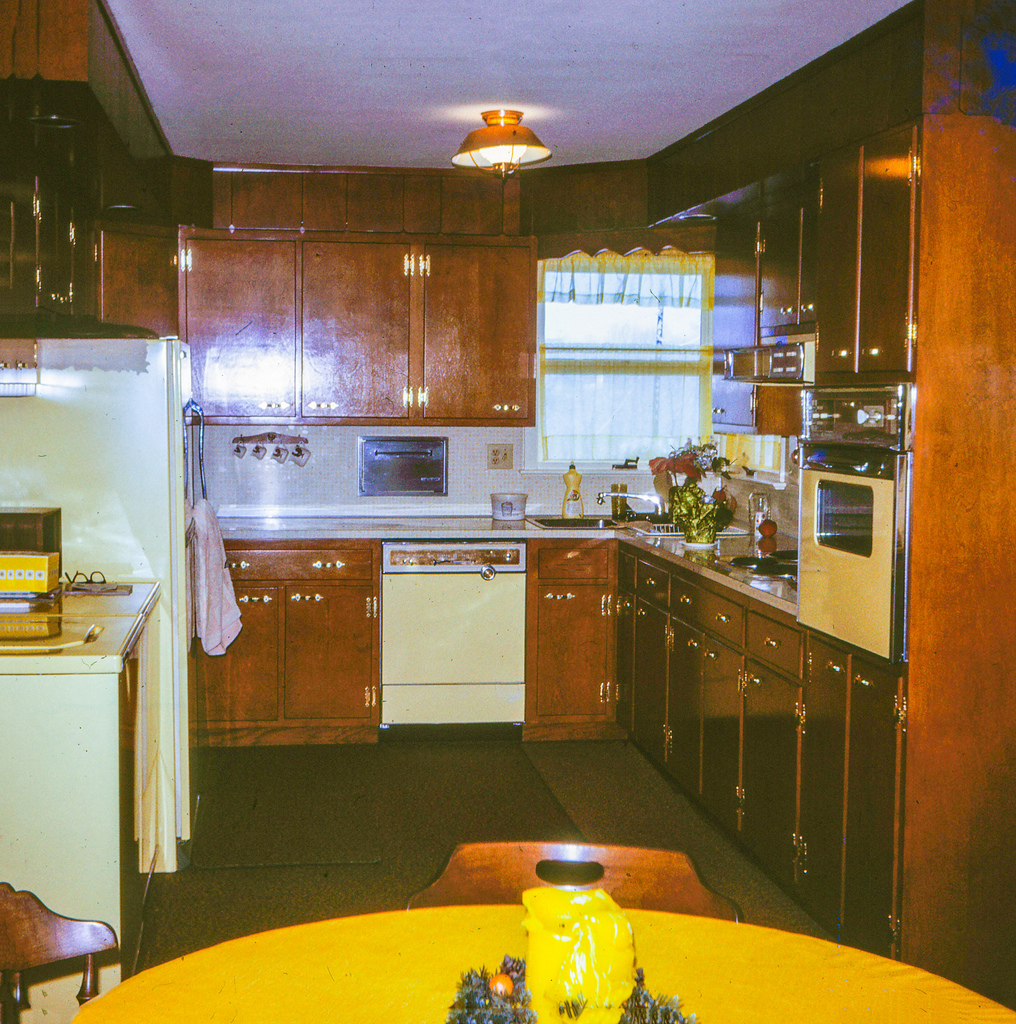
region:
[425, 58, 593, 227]
light on the ceiling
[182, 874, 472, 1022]
table in the room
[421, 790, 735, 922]
top of a chair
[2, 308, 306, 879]
fridge in the room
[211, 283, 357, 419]
light hitting the cabinets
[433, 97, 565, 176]
light fixture hanging from the ceiling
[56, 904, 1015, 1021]
the tabletop is yellow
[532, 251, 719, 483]
window in the kitchen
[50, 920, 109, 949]
light glare on the chair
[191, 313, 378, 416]
light glares on the cabinets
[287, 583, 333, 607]
gold handle on the cabinet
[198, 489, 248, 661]
towel is hanging up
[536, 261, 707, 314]
fabric hanging on the window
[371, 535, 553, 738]
off white dishwasher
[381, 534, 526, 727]
under counter dishwasher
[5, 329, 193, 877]
refrigerator, freezer in the kitchen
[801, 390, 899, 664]
gold colored wall oven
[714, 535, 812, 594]
counter top range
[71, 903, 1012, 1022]
yellow table cloth on kitchen table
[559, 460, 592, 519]
yellow bottle of dishwashing detergent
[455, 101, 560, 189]
orange and white ceiling light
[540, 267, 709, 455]
cafe curtain and valance over kitchen sink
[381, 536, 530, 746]
the dishwasher is old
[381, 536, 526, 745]
the dishwasher is yellow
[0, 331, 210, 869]
the refrigerator is old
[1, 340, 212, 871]
the refrigerator is yellow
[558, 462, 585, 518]
the bottle is yellow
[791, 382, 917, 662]
the oven is old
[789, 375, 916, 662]
the oven is yellow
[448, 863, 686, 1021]
Yellow candle with evergreens on table.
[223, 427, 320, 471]
Cup holder hanging on wall.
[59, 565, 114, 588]
Glasses sitting on counter.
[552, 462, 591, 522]
Dish soap on sink.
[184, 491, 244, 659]
Kitchen towel hanging off refrigerator handle.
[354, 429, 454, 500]
Oven door in wall.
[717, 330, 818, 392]
Stove hood under cabinets.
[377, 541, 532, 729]
Tan dishwasher in cabinets.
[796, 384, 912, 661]
Yellow oven above cabinets.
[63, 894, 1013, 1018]
a round yellow wooden table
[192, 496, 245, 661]
a towel hanging on the refrigerator door handle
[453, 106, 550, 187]
an illuminated light hanging on the ceiling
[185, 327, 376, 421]
light shining on the cabinet doors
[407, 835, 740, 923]
brown wooden chair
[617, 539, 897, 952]
line of cabinet doors and drawers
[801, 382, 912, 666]
a silver and cream colored oven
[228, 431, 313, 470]
cups hanging on the wall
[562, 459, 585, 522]
a yellow dish detergent bottle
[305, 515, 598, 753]
oven above the ground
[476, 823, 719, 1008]
item on the table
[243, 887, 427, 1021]
yellow table under object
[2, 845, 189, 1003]
chair in the kitchen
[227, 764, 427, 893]
ground under the oven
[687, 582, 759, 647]
handle on the object